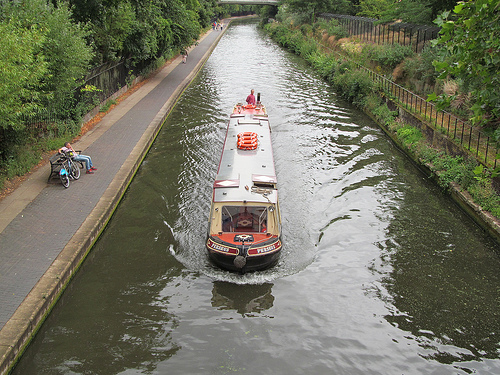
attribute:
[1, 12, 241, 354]
pathway — long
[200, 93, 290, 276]
boat — long, narrow, white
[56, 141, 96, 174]
man — seated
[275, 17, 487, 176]
fence — long, metal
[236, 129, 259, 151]
lifeboats — red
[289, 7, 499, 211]
fence — black, line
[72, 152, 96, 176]
jeans — blue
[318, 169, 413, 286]
water — calm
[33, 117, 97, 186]
bench — small, park